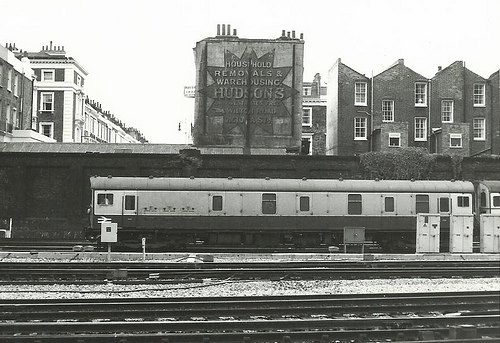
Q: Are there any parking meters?
A: No, there are no parking meters.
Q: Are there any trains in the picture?
A: Yes, there is a train.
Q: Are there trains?
A: Yes, there is a train.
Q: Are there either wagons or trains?
A: Yes, there is a train.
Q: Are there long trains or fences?
A: Yes, there is a long train.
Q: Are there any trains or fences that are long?
A: Yes, the train is long.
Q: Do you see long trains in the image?
A: Yes, there is a long train.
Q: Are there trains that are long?
A: Yes, there is a train that is long.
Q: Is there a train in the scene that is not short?
A: Yes, there is a long train.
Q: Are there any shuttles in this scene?
A: No, there are no shuttles.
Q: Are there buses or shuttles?
A: No, there are no shuttles or buses.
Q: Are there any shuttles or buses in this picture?
A: No, there are no shuttles or buses.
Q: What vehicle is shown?
A: The vehicle is a train.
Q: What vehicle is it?
A: The vehicle is a train.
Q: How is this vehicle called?
A: This is a train.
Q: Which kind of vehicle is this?
A: This is a train.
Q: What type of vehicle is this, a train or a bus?
A: This is a train.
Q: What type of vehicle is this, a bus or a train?
A: This is a train.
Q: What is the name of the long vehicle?
A: The vehicle is a train.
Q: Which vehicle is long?
A: The vehicle is a train.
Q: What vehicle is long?
A: The vehicle is a train.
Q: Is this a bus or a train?
A: This is a train.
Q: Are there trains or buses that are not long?
A: No, there is a train but it is long.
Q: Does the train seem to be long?
A: Yes, the train is long.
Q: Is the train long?
A: Yes, the train is long.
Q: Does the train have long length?
A: Yes, the train is long.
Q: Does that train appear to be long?
A: Yes, the train is long.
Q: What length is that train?
A: The train is long.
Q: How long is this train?
A: The train is long.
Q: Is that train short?
A: No, the train is long.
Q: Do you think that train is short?
A: No, the train is long.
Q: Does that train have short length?
A: No, the train is long.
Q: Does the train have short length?
A: No, the train is long.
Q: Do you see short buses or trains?
A: No, there is a train but it is long.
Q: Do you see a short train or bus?
A: No, there is a train but it is long.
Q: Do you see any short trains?
A: No, there is a train but it is long.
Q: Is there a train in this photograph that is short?
A: No, there is a train but it is long.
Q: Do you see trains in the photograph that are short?
A: No, there is a train but it is long.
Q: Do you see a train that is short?
A: No, there is a train but it is long.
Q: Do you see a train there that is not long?
A: No, there is a train but it is long.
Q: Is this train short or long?
A: The train is long.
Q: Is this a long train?
A: Yes, this is a long train.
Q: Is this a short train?
A: No, this is a long train.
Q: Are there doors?
A: Yes, there is a door.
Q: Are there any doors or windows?
A: Yes, there is a door.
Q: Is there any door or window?
A: Yes, there is a door.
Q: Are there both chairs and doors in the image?
A: No, there is a door but no chairs.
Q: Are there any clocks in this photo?
A: No, there are no clocks.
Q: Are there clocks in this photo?
A: No, there are no clocks.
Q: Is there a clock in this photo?
A: No, there are no clocks.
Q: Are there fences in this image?
A: No, there are no fences.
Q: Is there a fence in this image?
A: No, there are no fences.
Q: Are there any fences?
A: No, there are no fences.